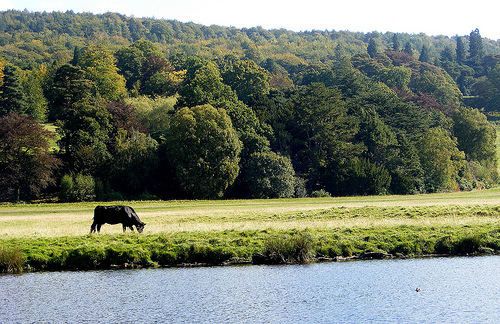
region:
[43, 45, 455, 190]
row of trees with bright green leaves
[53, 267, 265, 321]
small ripples on surface of water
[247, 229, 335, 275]
small bush growing beside river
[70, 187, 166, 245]
black cow grazing in field beside water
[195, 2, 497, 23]
bright blue sky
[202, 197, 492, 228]
grass growing in field on shore of river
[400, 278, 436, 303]
small bird floating on water surface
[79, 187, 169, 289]
large cow on shore of river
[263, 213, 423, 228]
dirt path beside river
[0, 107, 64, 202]
tree with red leaves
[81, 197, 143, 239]
black cow standing on grass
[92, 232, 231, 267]
grass growing by water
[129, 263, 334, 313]
calm clear blue water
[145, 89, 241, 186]
tree with green leaves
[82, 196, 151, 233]
cow standing by water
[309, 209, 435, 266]
patches of dirt in grass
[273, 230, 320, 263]
bush growing by water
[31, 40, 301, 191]
forest of trees behind the cow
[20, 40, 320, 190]
green trees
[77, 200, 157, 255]
cow eating green grass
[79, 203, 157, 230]
cow grazing on grass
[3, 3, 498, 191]
a forest with lots of trees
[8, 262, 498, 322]
calm body of water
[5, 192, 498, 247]
grass the cow is grazing on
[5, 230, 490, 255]
embankment next to the body of water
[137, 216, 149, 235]
the cow's head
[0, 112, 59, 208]
tree on left side with dark red leaves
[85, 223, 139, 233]
the cow's legs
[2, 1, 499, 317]
it's a bright sunny day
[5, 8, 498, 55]
flat stand of trees in the background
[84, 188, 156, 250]
LONE BLACK COW BY WATER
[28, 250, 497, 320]
CALM BLUE WATER RIVER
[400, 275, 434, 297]
OBJECT FLOATING DOWN THE RIVER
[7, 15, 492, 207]
THICK GREEN TREES BEHIND FIELD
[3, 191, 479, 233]
SHORT BRIGHT GREEN GRASS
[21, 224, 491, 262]
DARK GREEN VEGETATION BY WATER'S EDGE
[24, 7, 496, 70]
BRIGHT SKY WITH SOME CLOUDS ABOVE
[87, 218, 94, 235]
HIND LEG OF DARK COW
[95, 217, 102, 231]
HIND LEG OF DARK COW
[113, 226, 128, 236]
FRONT LEG OF DARK COW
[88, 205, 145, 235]
a black cow eating grass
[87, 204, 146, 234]
a cow standing on the side of a lake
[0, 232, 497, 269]
green grass on the side of the river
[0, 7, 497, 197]
natural feature of trees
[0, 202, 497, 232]
a black cow standing on a path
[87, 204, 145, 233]
a cow grazing beside the lake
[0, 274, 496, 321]
a lake with blue water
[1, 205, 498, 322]
one black cow eating green grass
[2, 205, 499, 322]
a loose black cow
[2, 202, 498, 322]
a cow on a ranch